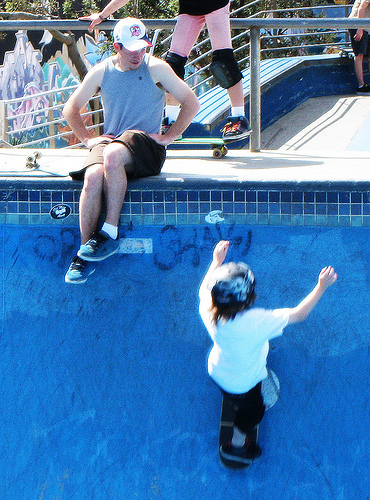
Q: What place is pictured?
A: It is a swimming pool.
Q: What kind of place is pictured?
A: It is a swimming pool.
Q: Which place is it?
A: It is a swimming pool.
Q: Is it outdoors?
A: Yes, it is outdoors.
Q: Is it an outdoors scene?
A: Yes, it is outdoors.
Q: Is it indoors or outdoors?
A: It is outdoors.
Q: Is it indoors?
A: No, it is outdoors.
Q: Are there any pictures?
A: No, there are no pictures.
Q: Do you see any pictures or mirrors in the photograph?
A: No, there are no pictures or mirrors.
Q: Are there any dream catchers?
A: No, there are no dream catchers.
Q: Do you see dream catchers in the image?
A: No, there are no dream catchers.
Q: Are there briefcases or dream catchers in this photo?
A: No, there are no dream catchers or briefcases.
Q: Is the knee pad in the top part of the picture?
A: Yes, the knee pad is in the top of the image.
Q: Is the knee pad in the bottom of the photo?
A: No, the knee pad is in the top of the image.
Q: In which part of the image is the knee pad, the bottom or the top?
A: The knee pad is in the top of the image.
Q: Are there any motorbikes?
A: No, there are no motorbikes.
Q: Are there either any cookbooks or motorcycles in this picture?
A: No, there are no motorcycles or cookbooks.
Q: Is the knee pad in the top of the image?
A: Yes, the knee pad is in the top of the image.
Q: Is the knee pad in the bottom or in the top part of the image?
A: The knee pad is in the top of the image.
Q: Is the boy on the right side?
A: Yes, the boy is on the right of the image.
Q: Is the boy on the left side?
A: No, the boy is on the right of the image.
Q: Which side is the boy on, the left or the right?
A: The boy is on the right of the image.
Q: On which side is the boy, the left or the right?
A: The boy is on the right of the image.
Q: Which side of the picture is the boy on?
A: The boy is on the right of the image.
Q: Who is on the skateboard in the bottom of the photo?
A: The boy is on the skateboard.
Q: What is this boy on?
A: The boy is on the skateboard.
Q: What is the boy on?
A: The boy is on the skateboard.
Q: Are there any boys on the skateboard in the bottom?
A: Yes, there is a boy on the skateboard.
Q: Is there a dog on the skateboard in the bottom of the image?
A: No, there is a boy on the skateboard.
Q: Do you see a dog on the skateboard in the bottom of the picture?
A: No, there is a boy on the skateboard.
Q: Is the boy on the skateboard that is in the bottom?
A: Yes, the boy is on the skateboard.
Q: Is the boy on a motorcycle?
A: No, the boy is on the skateboard.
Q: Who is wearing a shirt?
A: The boy is wearing a shirt.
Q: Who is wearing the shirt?
A: The boy is wearing a shirt.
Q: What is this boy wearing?
A: The boy is wearing a shirt.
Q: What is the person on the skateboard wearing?
A: The boy is wearing a shirt.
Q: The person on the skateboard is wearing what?
A: The boy is wearing a shirt.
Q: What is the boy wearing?
A: The boy is wearing a shirt.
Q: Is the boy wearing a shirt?
A: Yes, the boy is wearing a shirt.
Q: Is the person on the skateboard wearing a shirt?
A: Yes, the boy is wearing a shirt.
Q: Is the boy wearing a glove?
A: No, the boy is wearing a shirt.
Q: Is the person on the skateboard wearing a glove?
A: No, the boy is wearing a shirt.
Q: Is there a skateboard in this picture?
A: Yes, there is a skateboard.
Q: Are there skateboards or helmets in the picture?
A: Yes, there is a skateboard.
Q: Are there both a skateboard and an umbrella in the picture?
A: No, there is a skateboard but no umbrellas.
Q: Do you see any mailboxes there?
A: No, there are no mailboxes.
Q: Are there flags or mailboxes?
A: No, there are no mailboxes or flags.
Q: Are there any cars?
A: No, there are no cars.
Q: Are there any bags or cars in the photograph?
A: No, there are no cars or bags.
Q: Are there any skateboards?
A: Yes, there is a skateboard.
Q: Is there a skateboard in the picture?
A: Yes, there is a skateboard.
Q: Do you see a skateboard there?
A: Yes, there is a skateboard.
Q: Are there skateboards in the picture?
A: Yes, there is a skateboard.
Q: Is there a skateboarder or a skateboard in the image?
A: Yes, there is a skateboard.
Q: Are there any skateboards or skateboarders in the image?
A: Yes, there is a skateboard.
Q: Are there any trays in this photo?
A: No, there are no trays.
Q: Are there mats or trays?
A: No, there are no trays or mats.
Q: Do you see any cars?
A: No, there are no cars.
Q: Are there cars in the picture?
A: No, there are no cars.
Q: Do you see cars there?
A: No, there are no cars.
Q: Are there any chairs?
A: No, there are no chairs.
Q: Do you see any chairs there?
A: No, there are no chairs.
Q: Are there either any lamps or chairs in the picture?
A: No, there are no chairs or lamps.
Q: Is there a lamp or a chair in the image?
A: No, there are no chairs or lamps.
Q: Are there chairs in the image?
A: No, there are no chairs.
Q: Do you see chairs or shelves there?
A: No, there are no chairs or shelves.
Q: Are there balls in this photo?
A: No, there are no balls.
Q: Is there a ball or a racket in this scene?
A: No, there are no balls or rackets.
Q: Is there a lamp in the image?
A: No, there are no lamps.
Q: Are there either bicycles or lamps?
A: No, there are no lamps or bicycles.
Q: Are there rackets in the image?
A: No, there are no rackets.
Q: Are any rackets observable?
A: No, there are no rackets.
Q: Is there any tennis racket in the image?
A: No, there are no rackets.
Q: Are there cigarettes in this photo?
A: No, there are no cigarettes.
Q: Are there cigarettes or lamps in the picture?
A: No, there are no cigarettes or lamps.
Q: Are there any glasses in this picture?
A: No, there are no glasses.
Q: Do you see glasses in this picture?
A: No, there are no glasses.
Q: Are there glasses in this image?
A: No, there are no glasses.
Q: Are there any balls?
A: No, there are no balls.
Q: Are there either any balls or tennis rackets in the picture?
A: No, there are no balls or tennis rackets.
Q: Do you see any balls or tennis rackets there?
A: No, there are no balls or tennis rackets.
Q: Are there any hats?
A: Yes, there is a hat.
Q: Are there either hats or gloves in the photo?
A: Yes, there is a hat.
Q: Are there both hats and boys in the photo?
A: Yes, there are both a hat and a boy.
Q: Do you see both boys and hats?
A: Yes, there are both a hat and a boy.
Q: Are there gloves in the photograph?
A: No, there are no gloves.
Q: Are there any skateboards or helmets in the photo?
A: Yes, there is a skateboard.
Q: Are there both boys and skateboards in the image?
A: Yes, there are both a skateboard and a boy.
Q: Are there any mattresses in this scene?
A: No, there are no mattresses.